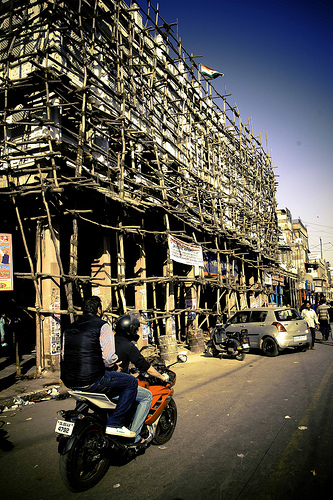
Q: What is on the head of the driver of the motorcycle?
A: A helmet.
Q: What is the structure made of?
A: Sticks.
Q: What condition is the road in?
A: Dirty.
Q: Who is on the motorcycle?
A: Two people.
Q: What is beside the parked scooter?
A: A car.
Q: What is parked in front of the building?
A: A tan car.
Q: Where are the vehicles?
A: Street.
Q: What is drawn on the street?
A: Yellow line.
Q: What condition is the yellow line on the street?
A: Faded.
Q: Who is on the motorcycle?
A: Two people in jeans.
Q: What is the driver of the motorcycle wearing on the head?
A: Helmet.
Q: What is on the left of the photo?
A: Tall building.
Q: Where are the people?
A: Street.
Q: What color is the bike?
A: Red.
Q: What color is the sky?
A: Blue.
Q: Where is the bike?
A: On the road.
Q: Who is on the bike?
A: Two men.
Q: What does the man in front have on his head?
A: Helmet.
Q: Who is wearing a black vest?
A: The man on the back of the bike.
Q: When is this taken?
A: During the daytime.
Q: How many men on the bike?
A: Two.